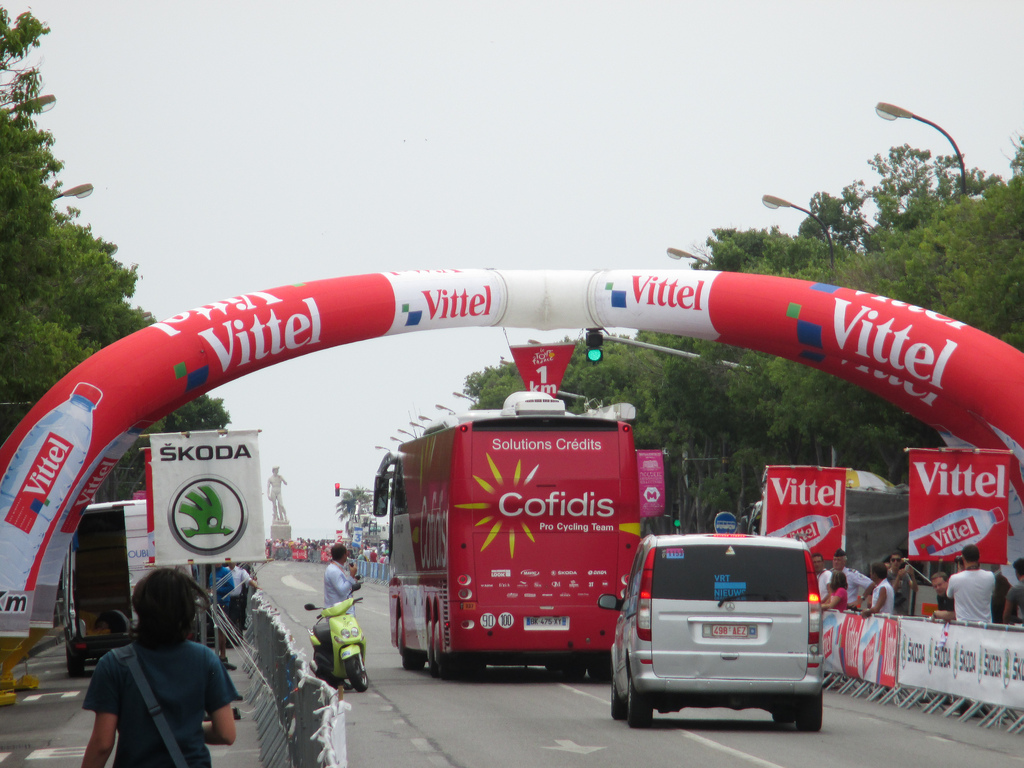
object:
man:
[939, 538, 1008, 632]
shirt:
[833, 564, 876, 617]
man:
[852, 546, 908, 638]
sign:
[131, 406, 283, 576]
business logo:
[132, 414, 273, 580]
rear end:
[581, 486, 871, 755]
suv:
[583, 519, 843, 733]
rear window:
[629, 528, 820, 610]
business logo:
[892, 428, 1020, 578]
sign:
[896, 439, 1016, 574]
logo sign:
[175, 294, 334, 375]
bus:
[369, 358, 671, 692]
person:
[55, 562, 252, 767]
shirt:
[83, 644, 241, 766]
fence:
[812, 616, 1023, 736]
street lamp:
[865, 98, 907, 128]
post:
[906, 113, 983, 196]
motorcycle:
[292, 595, 378, 699]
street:
[262, 549, 1023, 766]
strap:
[113, 640, 201, 768]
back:
[83, 640, 235, 767]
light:
[805, 590, 825, 608]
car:
[596, 508, 841, 738]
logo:
[159, 471, 250, 560]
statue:
[263, 466, 296, 549]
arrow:
[548, 729, 601, 765]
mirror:
[369, 467, 397, 523]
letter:
[233, 317, 257, 369]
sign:
[1, 244, 1023, 650]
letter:
[247, 310, 275, 364]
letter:
[282, 306, 316, 355]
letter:
[421, 284, 447, 324]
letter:
[625, 266, 655, 310]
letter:
[902, 341, 937, 383]